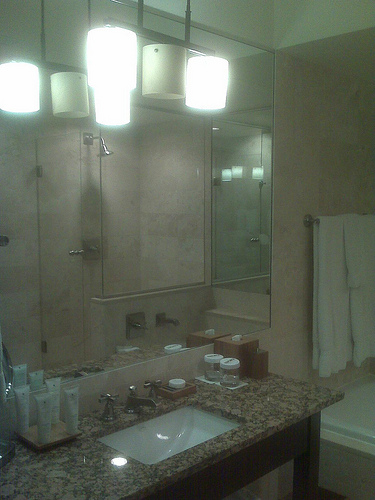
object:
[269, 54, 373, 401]
wall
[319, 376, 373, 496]
tub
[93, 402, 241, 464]
bowl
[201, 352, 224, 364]
lid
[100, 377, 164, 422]
faucet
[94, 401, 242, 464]
sink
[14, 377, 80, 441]
tubes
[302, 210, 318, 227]
bar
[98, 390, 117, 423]
knob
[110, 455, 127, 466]
spot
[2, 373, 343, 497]
counter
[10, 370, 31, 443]
bottles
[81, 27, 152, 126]
bathroom lights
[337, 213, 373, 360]
towel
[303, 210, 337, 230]
rack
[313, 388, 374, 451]
bathtub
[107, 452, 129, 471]
light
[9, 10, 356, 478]
bathroom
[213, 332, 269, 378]
tissue box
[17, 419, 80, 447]
plate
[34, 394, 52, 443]
container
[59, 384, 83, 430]
container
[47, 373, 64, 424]
container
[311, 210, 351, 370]
towel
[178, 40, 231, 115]
light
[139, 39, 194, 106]
light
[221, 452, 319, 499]
cabinet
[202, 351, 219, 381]
glass jar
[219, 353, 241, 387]
glass jar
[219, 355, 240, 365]
lid